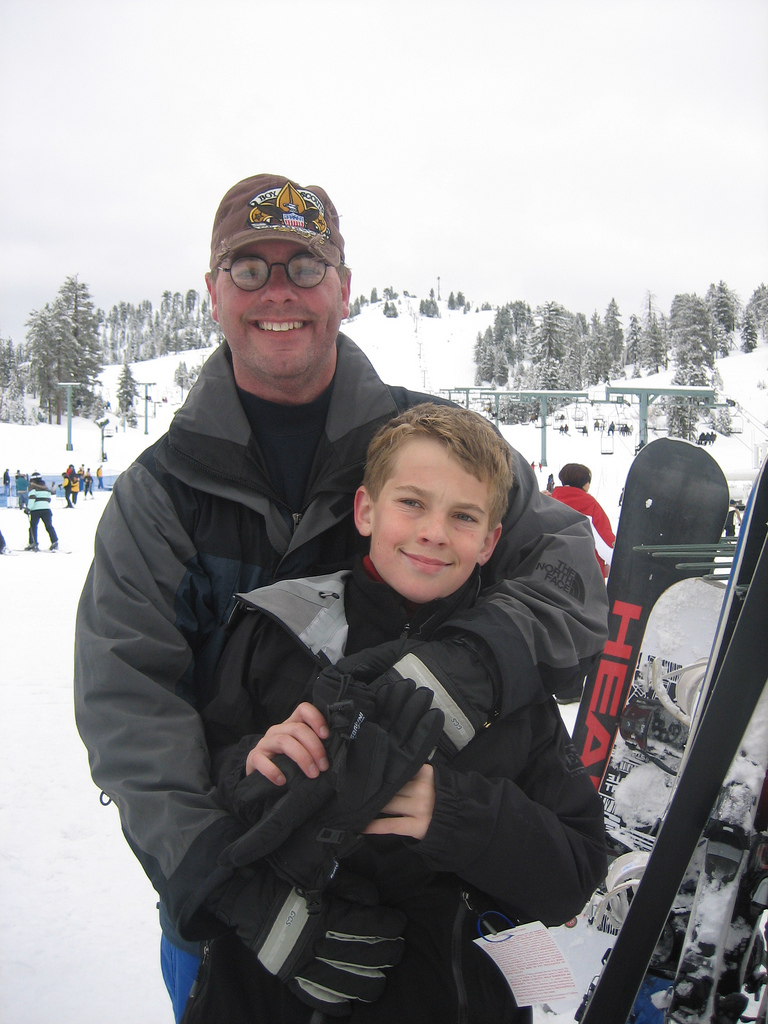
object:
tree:
[116, 362, 137, 423]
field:
[0, 299, 764, 1024]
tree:
[51, 268, 108, 421]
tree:
[30, 301, 83, 421]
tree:
[122, 299, 143, 349]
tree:
[154, 293, 172, 347]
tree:
[663, 323, 706, 436]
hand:
[208, 871, 408, 1008]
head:
[349, 403, 514, 606]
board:
[549, 436, 731, 868]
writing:
[576, 595, 643, 797]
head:
[197, 173, 346, 375]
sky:
[0, 0, 766, 352]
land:
[0, 288, 767, 1024]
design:
[249, 183, 330, 246]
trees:
[476, 284, 764, 401]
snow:
[475, 339, 489, 380]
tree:
[475, 339, 489, 380]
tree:
[492, 347, 510, 391]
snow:
[492, 347, 510, 391]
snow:
[644, 314, 664, 375]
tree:
[644, 314, 664, 375]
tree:
[626, 310, 646, 376]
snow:
[626, 310, 646, 376]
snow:
[600, 295, 624, 375]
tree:
[600, 295, 624, 375]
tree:
[584, 309, 612, 388]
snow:
[584, 309, 612, 388]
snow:
[733, 307, 755, 354]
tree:
[733, 307, 755, 354]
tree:
[113, 359, 132, 414]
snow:
[113, 359, 132, 414]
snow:
[528, 306, 563, 393]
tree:
[528, 306, 563, 393]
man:
[67, 173, 610, 1016]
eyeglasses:
[211, 250, 342, 293]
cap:
[200, 173, 347, 268]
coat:
[69, 342, 614, 956]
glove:
[228, 870, 418, 1012]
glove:
[355, 633, 503, 770]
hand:
[355, 633, 503, 762]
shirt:
[232, 381, 341, 535]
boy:
[190, 403, 611, 1014]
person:
[23, 471, 60, 553]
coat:
[18, 479, 49, 511]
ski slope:
[0, 288, 768, 1021]